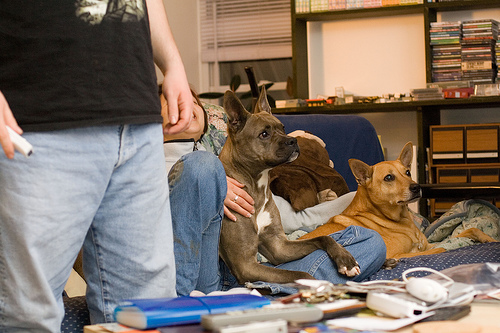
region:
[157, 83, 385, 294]
a person sitting on the couch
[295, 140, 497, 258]
dog sitting on the couch on the right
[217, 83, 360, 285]
dog sitting on the couch on the person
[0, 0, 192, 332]
a person standing up playing Wii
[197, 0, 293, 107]
a window in the background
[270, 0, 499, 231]
a large desk cabinet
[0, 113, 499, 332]
a blue futon couch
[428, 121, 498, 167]
a CD holder on the desk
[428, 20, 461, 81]
a stack of CDs on the desk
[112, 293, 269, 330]
a blue case on the coffee table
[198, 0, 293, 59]
white window blinds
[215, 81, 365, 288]
dark brown dog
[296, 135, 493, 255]
light brown dog lying down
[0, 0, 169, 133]
black tee shirt on man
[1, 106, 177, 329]
light colored blue jeans on man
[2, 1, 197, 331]
bottom half of man standing up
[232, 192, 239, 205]
silver ring on hand of women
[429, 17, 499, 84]
pile of CD cases on a shelf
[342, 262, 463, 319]
white Wii remote on table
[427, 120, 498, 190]
brown wooden boxes against wall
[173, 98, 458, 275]
two dogs sitting on couch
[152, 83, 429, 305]
two brown dogs together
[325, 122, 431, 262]
tan dog laying on couch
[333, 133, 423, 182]
pointy tan ears of dog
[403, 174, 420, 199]
small black nose of dog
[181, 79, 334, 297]
brown dog laying on couch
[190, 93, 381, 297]
brown dog laying on man's leg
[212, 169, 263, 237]
hand on side of dog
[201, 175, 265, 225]
human hand with ring on it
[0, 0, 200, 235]
man holding wii controller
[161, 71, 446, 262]
two dogs laying on couch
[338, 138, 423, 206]
head of tan dog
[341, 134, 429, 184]
perky ears of tan dog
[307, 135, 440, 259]
tan dog laying down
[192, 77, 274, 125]
perky ears of brown dog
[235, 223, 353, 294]
long legs of brown dog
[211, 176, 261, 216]
ring on man's hand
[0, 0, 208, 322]
man standing in jeans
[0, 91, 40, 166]
wii remote in man's hand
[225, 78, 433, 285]
two dogs sitting on a couch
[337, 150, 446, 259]
tan dog sitting on a couch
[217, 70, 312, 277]
brown dog sitting on a couch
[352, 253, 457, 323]
white wii remote on a table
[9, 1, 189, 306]
man wearing a black t-shirt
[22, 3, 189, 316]
man wearing blue jeans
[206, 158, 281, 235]
hand of a person on a dog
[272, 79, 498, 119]
ledge of a desk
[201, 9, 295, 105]
white venetian blinds on a window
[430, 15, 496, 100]
stacks of CDs on a shelf